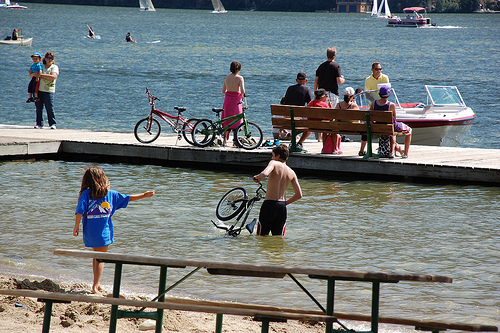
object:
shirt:
[75, 189, 131, 248]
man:
[314, 46, 345, 141]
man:
[272, 96, 299, 140]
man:
[365, 62, 389, 108]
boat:
[386, 7, 431, 28]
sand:
[1, 275, 328, 333]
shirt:
[38, 64, 59, 94]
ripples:
[0, 0, 499, 150]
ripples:
[0, 160, 500, 333]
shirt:
[365, 73, 390, 108]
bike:
[211, 177, 267, 237]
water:
[0, 159, 499, 333]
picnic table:
[0, 248, 499, 333]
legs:
[93, 245, 107, 284]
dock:
[0, 124, 499, 184]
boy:
[253, 144, 302, 236]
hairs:
[78, 167, 110, 199]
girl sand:
[69, 166, 156, 296]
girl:
[73, 167, 156, 295]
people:
[12, 28, 24, 41]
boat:
[0, 37, 33, 46]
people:
[355, 88, 373, 110]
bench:
[270, 104, 403, 160]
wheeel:
[216, 187, 249, 221]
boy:
[26, 52, 43, 103]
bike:
[134, 87, 209, 146]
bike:
[191, 93, 263, 150]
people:
[284, 72, 312, 150]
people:
[307, 88, 344, 154]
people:
[334, 87, 366, 156]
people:
[369, 85, 413, 158]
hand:
[253, 175, 261, 184]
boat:
[272, 83, 477, 146]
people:
[86, 27, 95, 41]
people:
[124, 32, 137, 44]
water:
[0, 2, 500, 148]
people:
[34, 52, 60, 130]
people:
[221, 61, 245, 147]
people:
[391, 14, 395, 19]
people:
[405, 14, 410, 19]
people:
[419, 14, 423, 18]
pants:
[257, 200, 287, 237]